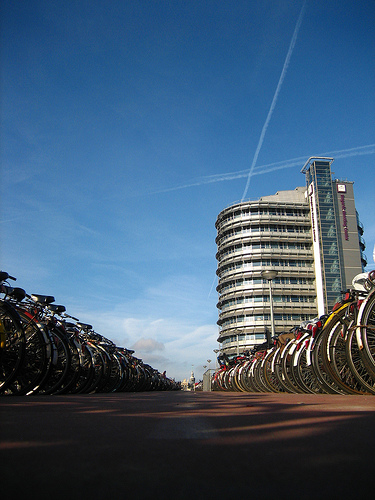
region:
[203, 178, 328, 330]
shiny brown building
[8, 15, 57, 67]
white clouds in blue sky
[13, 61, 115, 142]
white clouds in blue sky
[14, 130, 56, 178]
white clouds in blue sky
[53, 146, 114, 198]
white clouds in blue sky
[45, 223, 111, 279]
white clouds in blue sky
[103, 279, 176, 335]
white clouds in blue sky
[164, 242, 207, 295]
white clouds in blue sky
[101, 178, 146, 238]
white clouds in blue sky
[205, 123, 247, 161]
white clouds in blue sky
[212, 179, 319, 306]
large building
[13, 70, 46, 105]
white clouds in blue sky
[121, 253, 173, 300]
white clouds in blue sky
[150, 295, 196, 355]
white clouds in blue sky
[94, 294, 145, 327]
white clouds in blue sky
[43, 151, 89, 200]
white clouds in blue sky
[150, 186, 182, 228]
white clouds in blue sky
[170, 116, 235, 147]
white clouds in blue sky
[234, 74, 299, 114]
white clouds in blue sky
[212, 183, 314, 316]
shiny building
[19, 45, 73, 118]
white clouds in blue sky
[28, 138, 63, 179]
white clouds in blue sky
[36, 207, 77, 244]
white clouds in blue sky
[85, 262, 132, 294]
white clouds in blue sky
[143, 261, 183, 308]
white clouds in blue sky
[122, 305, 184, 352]
white clouds in blue sky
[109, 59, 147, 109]
white clouds in blue sky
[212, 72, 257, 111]
white clouds in blue sky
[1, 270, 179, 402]
A long row of bicycles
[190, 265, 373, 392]
A long row of bicycles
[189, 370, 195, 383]
A tall tower in the distance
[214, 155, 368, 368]
A very large building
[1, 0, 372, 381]
A clear blue sky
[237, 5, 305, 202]
a contrail from a jet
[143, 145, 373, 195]
a contrail from a jet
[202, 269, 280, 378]
a row of street lights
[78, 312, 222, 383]
some clouds in the sky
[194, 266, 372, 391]
some bikes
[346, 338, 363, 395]
tire of a bike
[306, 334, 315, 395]
tire on a bike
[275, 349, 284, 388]
tire on a bike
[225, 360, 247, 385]
tire on a bike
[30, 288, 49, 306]
seat on a bike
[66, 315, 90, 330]
seat on a bike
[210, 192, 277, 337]
tall building with windows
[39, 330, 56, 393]
tire on a bike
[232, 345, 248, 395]
tire on a bike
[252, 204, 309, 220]
windows on a building